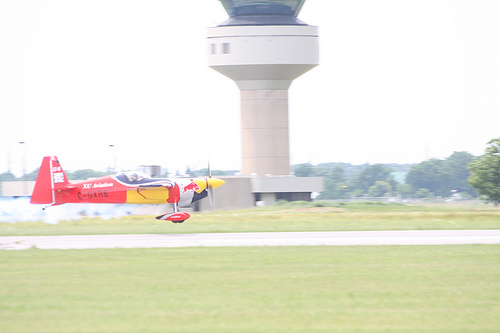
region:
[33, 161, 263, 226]
Red and yellow airplane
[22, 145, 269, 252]
Airplane taking off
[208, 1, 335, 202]
Control tower at airport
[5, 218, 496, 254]
Runway at airport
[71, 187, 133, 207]
C-Garb written on plane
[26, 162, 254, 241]
Single passenger air plane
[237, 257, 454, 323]
Grass on ground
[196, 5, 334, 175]
Air traffic controllers work in this tower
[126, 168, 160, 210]
This person is a pilot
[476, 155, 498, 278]
Trees and grass are green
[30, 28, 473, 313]
picture taken outdoors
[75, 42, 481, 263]
picture taken during the day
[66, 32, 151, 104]
the sky is light grey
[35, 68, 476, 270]
an airport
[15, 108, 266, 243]
a red and yellow plane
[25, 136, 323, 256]
the plane is taking off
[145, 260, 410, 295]
the runway is below the plane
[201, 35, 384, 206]
the control tower in the back of the plane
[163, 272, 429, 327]
the grass is cut short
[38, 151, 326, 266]
the plane is in the air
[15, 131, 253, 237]
small older single person air plane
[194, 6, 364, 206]
airport communication tower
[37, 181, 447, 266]
landing strip at airport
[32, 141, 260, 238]
red and yellow air plane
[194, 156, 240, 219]
propeller to a small red,white, and yellow airplane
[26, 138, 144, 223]
identifying decals on side of airplane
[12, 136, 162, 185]
light poles in background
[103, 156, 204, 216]
the cockpit of an airplane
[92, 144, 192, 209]
person flying a small plane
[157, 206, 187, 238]
tired for landing a small airplane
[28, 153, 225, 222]
Plane is taking off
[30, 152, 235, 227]
plane is in the air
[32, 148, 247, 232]
plane is over runway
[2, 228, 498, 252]
runway under the plane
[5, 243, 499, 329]
grass is near the runway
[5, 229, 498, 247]
runway is near the grass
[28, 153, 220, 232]
plane is red and yellow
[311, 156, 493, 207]
trees are in the back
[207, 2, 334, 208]
tower is behind the plane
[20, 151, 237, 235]
plane is in motion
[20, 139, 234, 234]
a plane near a tower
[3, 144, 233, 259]
a plane is above a landing strip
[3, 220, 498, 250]
landing strip is narrow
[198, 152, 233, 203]
propeller of plane is yellow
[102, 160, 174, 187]
window of pilot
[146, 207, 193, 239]
wheels of plane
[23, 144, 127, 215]
plane has white and black letters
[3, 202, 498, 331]
field of airport is cover with green grass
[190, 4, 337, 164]
control tower is round